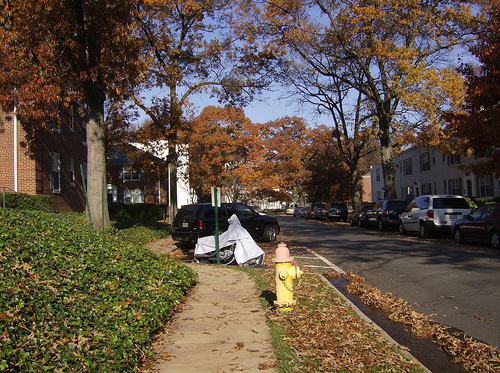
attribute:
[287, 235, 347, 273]
lines — white, street lines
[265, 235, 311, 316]
hydrant — yellow, red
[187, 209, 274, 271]
motorcycle — covered, parked, white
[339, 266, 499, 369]
leaves — brown, dead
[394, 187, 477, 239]
minivan — white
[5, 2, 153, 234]
tree — brown leafed, tall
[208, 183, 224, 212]
sign — street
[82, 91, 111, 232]
trunk — brown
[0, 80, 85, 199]
building — two-story, shadowed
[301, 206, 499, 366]
street — quiet, residential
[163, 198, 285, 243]
suv — black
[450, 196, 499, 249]
car — parked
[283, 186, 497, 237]
cars — parked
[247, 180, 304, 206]
bush — long low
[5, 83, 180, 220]
housing — large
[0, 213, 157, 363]
grass — thick